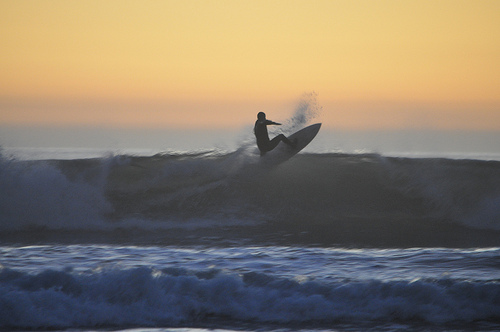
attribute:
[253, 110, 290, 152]
man — dark, surfing, bent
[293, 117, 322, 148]
surfboard — spraying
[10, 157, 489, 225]
wave — rolling, breaking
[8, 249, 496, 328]
ocean — white, calm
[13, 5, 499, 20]
sky — pink, blue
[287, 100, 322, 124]
water — white